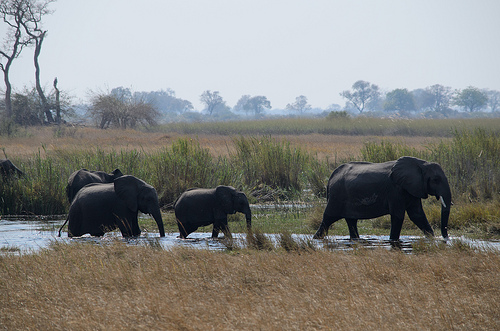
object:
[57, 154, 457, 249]
elephants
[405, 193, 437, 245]
leg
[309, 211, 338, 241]
legs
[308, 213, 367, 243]
legs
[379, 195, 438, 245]
legs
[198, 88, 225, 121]
tree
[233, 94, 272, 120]
tree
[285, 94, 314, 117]
tree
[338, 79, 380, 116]
tree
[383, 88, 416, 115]
tree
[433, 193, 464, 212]
tusk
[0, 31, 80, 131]
tree trucks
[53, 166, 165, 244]
elephants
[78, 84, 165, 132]
tree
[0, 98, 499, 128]
horizon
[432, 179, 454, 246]
trunk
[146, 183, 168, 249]
trunk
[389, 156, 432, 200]
ear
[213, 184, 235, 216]
ear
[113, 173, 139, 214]
ear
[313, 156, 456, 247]
elephant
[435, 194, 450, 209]
tusk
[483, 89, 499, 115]
tree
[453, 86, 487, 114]
tree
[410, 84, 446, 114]
tree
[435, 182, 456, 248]
elephant trunk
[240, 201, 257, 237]
elephant trunk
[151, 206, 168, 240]
elephant trunk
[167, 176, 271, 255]
elephant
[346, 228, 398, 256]
water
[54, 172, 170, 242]
elephant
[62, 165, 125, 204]
elephant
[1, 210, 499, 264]
water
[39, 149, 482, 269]
elephant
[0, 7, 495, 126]
sky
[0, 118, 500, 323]
marsh